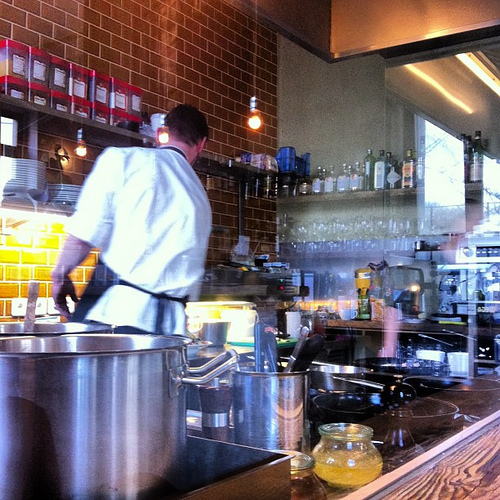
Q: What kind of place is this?
A: It is a restaurant.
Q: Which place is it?
A: It is a restaurant.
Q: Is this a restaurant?
A: Yes, it is a restaurant.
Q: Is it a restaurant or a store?
A: It is a restaurant.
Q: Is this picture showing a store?
A: No, the picture is showing a restaurant.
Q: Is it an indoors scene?
A: Yes, it is indoors.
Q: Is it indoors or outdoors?
A: It is indoors.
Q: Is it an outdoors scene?
A: No, it is indoors.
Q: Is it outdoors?
A: No, it is indoors.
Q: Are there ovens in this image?
A: No, there are no ovens.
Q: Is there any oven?
A: No, there are no ovens.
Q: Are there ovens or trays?
A: No, there are no ovens or trays.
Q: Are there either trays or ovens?
A: No, there are no ovens or trays.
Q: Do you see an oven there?
A: No, there are no ovens.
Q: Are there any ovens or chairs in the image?
A: No, there are no ovens or chairs.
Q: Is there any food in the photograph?
A: No, there is no food.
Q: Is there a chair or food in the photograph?
A: No, there are no food or chairs.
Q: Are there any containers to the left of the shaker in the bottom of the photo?
A: Yes, there is a container to the left of the grinder.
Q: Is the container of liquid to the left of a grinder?
A: Yes, the container is to the left of a grinder.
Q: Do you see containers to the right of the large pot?
A: Yes, there is a container to the right of the pot.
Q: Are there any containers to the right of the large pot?
A: Yes, there is a container to the right of the pot.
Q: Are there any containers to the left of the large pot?
A: No, the container is to the right of the pot.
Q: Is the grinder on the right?
A: Yes, the grinder is on the right of the image.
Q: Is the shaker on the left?
A: No, the shaker is on the right of the image.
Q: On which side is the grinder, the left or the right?
A: The grinder is on the right of the image.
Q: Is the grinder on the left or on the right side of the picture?
A: The grinder is on the right of the image.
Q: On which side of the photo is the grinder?
A: The grinder is on the right of the image.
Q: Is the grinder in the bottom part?
A: Yes, the grinder is in the bottom of the image.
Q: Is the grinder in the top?
A: No, the grinder is in the bottom of the image.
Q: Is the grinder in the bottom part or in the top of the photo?
A: The grinder is in the bottom of the image.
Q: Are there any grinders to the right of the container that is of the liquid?
A: Yes, there is a grinder to the right of the container.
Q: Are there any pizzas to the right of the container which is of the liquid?
A: No, there is a grinder to the right of the container.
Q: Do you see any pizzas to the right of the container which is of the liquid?
A: No, there is a grinder to the right of the container.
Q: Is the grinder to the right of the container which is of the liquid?
A: Yes, the grinder is to the right of the container.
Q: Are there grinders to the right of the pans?
A: Yes, there is a grinder to the right of the pans.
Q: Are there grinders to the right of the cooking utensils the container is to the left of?
A: Yes, there is a grinder to the right of the pans.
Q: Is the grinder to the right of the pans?
A: Yes, the grinder is to the right of the pans.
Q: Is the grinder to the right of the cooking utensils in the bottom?
A: Yes, the grinder is to the right of the pans.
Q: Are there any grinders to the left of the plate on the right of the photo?
A: Yes, there is a grinder to the left of the plate.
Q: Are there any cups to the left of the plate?
A: No, there is a grinder to the left of the plate.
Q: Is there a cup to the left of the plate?
A: No, there is a grinder to the left of the plate.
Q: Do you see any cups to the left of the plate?
A: No, there is a grinder to the left of the plate.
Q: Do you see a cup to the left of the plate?
A: No, there is a grinder to the left of the plate.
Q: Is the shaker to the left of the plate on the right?
A: Yes, the shaker is to the left of the plate.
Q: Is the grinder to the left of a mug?
A: No, the grinder is to the left of the plate.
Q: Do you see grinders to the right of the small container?
A: Yes, there is a grinder to the right of the container.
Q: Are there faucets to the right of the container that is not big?
A: No, there is a grinder to the right of the container.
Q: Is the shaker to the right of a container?
A: Yes, the shaker is to the right of a container.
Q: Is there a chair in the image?
A: No, there are no chairs.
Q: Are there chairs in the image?
A: No, there are no chairs.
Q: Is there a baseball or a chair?
A: No, there are no chairs or baseballs.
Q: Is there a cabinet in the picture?
A: No, there are no cabinets.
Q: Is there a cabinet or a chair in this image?
A: No, there are no cabinets or chairs.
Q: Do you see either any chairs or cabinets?
A: No, there are no cabinets or chairs.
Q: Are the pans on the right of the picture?
A: Yes, the pans are on the right of the image.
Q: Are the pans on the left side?
A: No, the pans are on the right of the image.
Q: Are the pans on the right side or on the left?
A: The pans are on the right of the image.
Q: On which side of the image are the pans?
A: The pans are on the right of the image.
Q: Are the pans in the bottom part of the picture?
A: Yes, the pans are in the bottom of the image.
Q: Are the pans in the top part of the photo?
A: No, the pans are in the bottom of the image.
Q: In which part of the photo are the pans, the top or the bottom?
A: The pans are in the bottom of the image.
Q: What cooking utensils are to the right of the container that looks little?
A: The cooking utensils are pans.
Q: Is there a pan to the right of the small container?
A: Yes, there are pans to the right of the container.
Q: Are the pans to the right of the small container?
A: Yes, the pans are to the right of the container.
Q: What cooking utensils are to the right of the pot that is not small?
A: The cooking utensils are pans.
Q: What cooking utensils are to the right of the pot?
A: The cooking utensils are pans.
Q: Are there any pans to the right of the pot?
A: Yes, there are pans to the right of the pot.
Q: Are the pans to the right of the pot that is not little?
A: Yes, the pans are to the right of the pot.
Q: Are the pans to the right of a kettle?
A: No, the pans are to the right of the pot.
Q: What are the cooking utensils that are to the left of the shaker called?
A: The cooking utensils are pans.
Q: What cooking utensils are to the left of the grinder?
A: The cooking utensils are pans.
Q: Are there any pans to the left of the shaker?
A: Yes, there are pans to the left of the shaker.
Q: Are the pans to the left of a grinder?
A: Yes, the pans are to the left of a grinder.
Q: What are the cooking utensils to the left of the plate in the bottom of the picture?
A: The cooking utensils are pans.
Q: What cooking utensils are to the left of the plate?
A: The cooking utensils are pans.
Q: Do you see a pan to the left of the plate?
A: Yes, there are pans to the left of the plate.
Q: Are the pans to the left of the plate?
A: Yes, the pans are to the left of the plate.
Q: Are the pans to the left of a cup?
A: No, the pans are to the left of the plate.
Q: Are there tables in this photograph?
A: Yes, there is a table.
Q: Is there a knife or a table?
A: Yes, there is a table.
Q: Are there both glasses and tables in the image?
A: Yes, there are both a table and glasses.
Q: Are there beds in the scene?
A: No, there are no beds.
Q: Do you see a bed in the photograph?
A: No, there are no beds.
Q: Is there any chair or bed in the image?
A: No, there are no beds or chairs.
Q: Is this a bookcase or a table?
A: This is a table.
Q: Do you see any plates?
A: Yes, there is a plate.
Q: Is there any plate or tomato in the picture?
A: Yes, there is a plate.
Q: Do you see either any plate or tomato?
A: Yes, there is a plate.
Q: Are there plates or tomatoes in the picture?
A: Yes, there is a plate.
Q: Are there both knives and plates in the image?
A: No, there is a plate but no knives.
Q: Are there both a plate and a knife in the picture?
A: No, there is a plate but no knives.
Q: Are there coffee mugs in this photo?
A: No, there are no coffee mugs.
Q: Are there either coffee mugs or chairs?
A: No, there are no coffee mugs or chairs.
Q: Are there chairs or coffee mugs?
A: No, there are no coffee mugs or chairs.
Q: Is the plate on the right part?
A: Yes, the plate is on the right of the image.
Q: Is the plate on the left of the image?
A: No, the plate is on the right of the image.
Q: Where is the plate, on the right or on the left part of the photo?
A: The plate is on the right of the image.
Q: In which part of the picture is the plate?
A: The plate is on the right of the image.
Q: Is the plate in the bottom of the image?
A: Yes, the plate is in the bottom of the image.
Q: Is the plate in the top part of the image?
A: No, the plate is in the bottom of the image.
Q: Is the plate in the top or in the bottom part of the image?
A: The plate is in the bottom of the image.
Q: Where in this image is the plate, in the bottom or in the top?
A: The plate is in the bottom of the image.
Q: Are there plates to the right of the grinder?
A: Yes, there is a plate to the right of the grinder.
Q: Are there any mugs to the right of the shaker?
A: No, there is a plate to the right of the shaker.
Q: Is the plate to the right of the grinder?
A: Yes, the plate is to the right of the grinder.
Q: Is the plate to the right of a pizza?
A: No, the plate is to the right of the grinder.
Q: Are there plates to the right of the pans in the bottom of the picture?
A: Yes, there is a plate to the right of the pans.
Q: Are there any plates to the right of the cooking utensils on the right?
A: Yes, there is a plate to the right of the pans.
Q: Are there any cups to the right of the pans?
A: No, there is a plate to the right of the pans.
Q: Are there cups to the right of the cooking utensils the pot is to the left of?
A: No, there is a plate to the right of the pans.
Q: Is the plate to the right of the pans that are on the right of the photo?
A: Yes, the plate is to the right of the pans.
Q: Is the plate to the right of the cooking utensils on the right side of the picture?
A: Yes, the plate is to the right of the pans.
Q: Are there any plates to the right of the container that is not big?
A: Yes, there is a plate to the right of the container.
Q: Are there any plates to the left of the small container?
A: No, the plate is to the right of the container.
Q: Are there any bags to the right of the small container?
A: No, there is a plate to the right of the container.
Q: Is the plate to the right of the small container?
A: Yes, the plate is to the right of the container.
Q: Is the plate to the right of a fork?
A: No, the plate is to the right of the container.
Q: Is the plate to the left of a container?
A: No, the plate is to the right of a container.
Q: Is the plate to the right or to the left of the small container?
A: The plate is to the right of the container.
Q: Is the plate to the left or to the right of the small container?
A: The plate is to the right of the container.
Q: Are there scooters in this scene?
A: No, there are no scooters.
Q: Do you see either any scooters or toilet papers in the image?
A: No, there are no scooters or toilet papers.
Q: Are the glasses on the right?
A: Yes, the glasses are on the right of the image.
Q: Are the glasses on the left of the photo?
A: No, the glasses are on the right of the image.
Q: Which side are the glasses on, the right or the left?
A: The glasses are on the right of the image.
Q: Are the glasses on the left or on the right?
A: The glasses are on the right of the image.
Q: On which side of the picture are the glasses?
A: The glasses are on the right of the image.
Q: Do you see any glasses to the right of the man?
A: Yes, there are glasses to the right of the man.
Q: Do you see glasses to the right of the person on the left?
A: Yes, there are glasses to the right of the man.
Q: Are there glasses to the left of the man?
A: No, the glasses are to the right of the man.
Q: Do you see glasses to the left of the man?
A: No, the glasses are to the right of the man.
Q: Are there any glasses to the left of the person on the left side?
A: No, the glasses are to the right of the man.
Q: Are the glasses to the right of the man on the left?
A: Yes, the glasses are to the right of the man.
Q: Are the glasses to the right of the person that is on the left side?
A: Yes, the glasses are to the right of the man.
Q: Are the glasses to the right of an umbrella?
A: No, the glasses are to the right of the man.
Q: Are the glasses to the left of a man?
A: No, the glasses are to the right of a man.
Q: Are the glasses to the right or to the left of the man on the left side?
A: The glasses are to the right of the man.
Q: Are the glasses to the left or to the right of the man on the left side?
A: The glasses are to the right of the man.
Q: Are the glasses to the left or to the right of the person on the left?
A: The glasses are to the right of the man.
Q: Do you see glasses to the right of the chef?
A: Yes, there are glasses to the right of the chef.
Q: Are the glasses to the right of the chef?
A: Yes, the glasses are to the right of the chef.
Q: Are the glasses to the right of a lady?
A: No, the glasses are to the right of the chef.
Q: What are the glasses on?
A: The glasses are on the wall.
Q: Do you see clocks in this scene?
A: No, there are no clocks.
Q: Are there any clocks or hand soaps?
A: No, there are no clocks or hand soaps.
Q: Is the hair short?
A: Yes, the hair is short.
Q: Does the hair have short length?
A: Yes, the hair is short.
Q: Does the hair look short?
A: Yes, the hair is short.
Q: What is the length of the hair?
A: The hair is short.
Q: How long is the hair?
A: The hair is short.